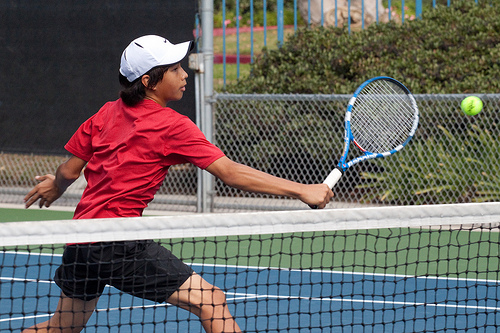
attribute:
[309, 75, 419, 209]
racket — blue, for tennis, white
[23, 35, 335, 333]
boy — playing tennis, young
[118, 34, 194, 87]
cap — white, baseball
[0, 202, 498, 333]
net — black, for tennis, white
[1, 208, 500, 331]
tennis court — blue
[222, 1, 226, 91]
post — blue, metal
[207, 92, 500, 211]
fence — chain link, silver, metal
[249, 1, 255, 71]
post — blue, metal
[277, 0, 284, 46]
post — blue, metal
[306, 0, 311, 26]
post — blue, metal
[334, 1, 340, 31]
post — blue, metal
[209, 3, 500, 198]
bush — green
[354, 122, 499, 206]
bush — green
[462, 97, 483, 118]
tennis ball — green, in motion, yellow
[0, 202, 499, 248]
edge — white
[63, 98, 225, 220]
shirt — red, short sleeved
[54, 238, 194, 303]
shorts — black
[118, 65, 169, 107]
hair — black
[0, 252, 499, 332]
part — blue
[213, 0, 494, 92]
fence — blue, metal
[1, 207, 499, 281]
area — green, out of bounds